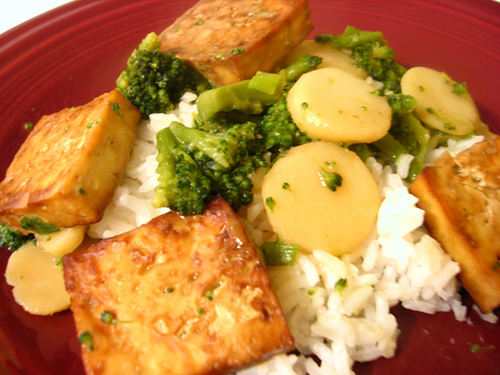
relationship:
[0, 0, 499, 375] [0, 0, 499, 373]
dish has food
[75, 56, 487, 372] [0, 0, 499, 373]
rice has food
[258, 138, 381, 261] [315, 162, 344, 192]
potato has broccoli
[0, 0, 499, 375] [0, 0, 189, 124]
dish has grooves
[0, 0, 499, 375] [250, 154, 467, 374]
dish has rice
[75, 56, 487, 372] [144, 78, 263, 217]
rice has broccoli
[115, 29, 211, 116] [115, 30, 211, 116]
broccoli has broccoli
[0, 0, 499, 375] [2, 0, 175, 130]
dish has lines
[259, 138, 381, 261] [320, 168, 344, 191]
potato has broccoli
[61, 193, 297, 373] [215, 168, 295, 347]
tofu has browning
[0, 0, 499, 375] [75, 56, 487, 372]
dish has rice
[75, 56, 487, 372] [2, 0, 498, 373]
rice under tofu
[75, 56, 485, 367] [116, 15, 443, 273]
rice under broccoli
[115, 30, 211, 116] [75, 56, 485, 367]
broccoli on top of rice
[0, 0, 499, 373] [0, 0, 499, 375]
food on top of dish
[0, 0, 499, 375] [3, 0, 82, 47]
dish has edge